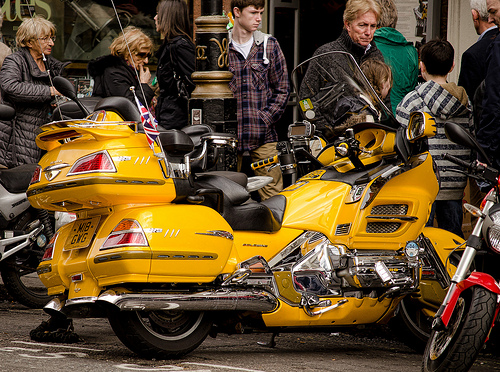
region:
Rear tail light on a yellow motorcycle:
[99, 217, 157, 252]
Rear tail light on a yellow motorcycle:
[38, 233, 58, 263]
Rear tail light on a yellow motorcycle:
[69, 149, 118, 175]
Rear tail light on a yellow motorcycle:
[28, 163, 43, 184]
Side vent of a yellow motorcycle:
[362, 200, 414, 235]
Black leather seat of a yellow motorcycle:
[200, 182, 297, 232]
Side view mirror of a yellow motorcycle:
[404, 106, 436, 141]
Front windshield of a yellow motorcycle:
[287, 47, 389, 127]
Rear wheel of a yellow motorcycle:
[110, 309, 226, 357]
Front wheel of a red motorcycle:
[424, 276, 499, 370]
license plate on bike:
[66, 216, 100, 253]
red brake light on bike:
[73, 152, 116, 170]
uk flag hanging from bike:
[134, 98, 164, 149]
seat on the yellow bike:
[193, 166, 266, 205]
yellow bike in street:
[24, 82, 472, 357]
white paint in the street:
[0, 337, 272, 369]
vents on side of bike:
[362, 197, 411, 237]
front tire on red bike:
[432, 274, 497, 366]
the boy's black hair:
[425, 41, 457, 75]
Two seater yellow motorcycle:
[35, 42, 475, 355]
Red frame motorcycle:
[419, 115, 499, 368]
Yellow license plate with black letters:
[61, 210, 102, 252]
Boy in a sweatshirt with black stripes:
[393, 37, 476, 240]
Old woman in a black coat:
[2, 13, 73, 179]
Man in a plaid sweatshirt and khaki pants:
[224, 0, 291, 198]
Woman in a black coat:
[150, 0, 198, 135]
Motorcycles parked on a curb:
[0, 61, 498, 370]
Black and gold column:
[185, 0, 240, 172]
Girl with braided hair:
[354, 55, 392, 128]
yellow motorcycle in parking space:
[21, 63, 479, 332]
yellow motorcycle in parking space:
[0, 56, 482, 331]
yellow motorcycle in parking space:
[18, 85, 465, 345]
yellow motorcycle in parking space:
[36, 84, 456, 341]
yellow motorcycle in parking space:
[0, 90, 443, 337]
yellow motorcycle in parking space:
[29, 85, 444, 352]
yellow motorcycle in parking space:
[12, 125, 440, 340]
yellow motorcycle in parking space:
[29, 84, 481, 344]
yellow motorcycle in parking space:
[99, 86, 445, 354]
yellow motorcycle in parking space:
[3, 84, 437, 354]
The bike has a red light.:
[63, 148, 118, 181]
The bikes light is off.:
[68, 147, 128, 187]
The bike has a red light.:
[22, 161, 44, 186]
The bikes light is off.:
[23, 162, 41, 185]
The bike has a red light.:
[99, 213, 143, 252]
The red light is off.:
[103, 216, 158, 261]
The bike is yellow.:
[19, 109, 446, 339]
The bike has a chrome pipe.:
[88, 279, 281, 328]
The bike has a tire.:
[83, 296, 217, 363]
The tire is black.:
[103, 299, 221, 355]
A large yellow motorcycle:
[54, 101, 437, 273]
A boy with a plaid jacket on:
[212, 27, 291, 154]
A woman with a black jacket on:
[8, 22, 70, 180]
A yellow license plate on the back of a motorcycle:
[54, 199, 103, 274]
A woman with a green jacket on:
[346, 23, 421, 109]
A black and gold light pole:
[183, 13, 235, 151]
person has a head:
[226, 0, 266, 35]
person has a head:
[340, 1, 380, 46]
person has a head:
[376, 1, 398, 26]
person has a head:
[415, 40, 455, 80]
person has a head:
[352, 59, 392, 97]